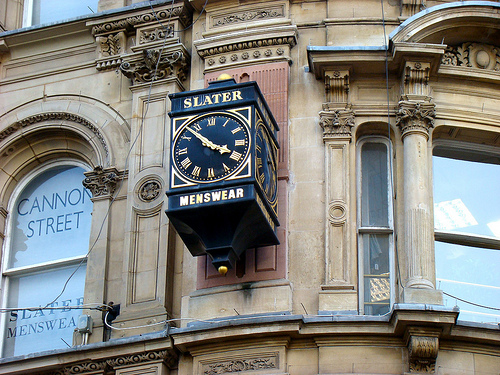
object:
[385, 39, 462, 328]
column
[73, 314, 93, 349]
electrical box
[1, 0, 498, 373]
pillar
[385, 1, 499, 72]
arch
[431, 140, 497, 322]
window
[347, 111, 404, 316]
window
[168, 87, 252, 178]
blue clock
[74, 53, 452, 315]
building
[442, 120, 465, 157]
ground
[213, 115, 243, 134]
roman numerals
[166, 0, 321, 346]
wall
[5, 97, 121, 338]
arch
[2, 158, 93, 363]
arched window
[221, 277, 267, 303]
black mark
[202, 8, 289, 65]
decorations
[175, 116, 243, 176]
numbers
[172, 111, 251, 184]
clock face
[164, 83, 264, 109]
brandname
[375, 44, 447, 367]
design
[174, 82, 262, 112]
slater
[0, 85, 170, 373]
street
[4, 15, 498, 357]
exterior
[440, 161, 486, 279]
lights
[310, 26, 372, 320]
stone column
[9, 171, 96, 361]
poster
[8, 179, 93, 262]
streetname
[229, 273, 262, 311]
spot